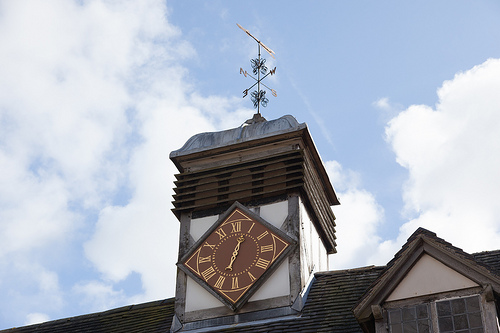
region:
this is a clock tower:
[116, 180, 287, 312]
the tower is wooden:
[73, 91, 345, 327]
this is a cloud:
[49, 73, 158, 215]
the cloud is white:
[11, 7, 105, 109]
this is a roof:
[343, 279, 352, 310]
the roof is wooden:
[337, 289, 345, 321]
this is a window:
[405, 306, 434, 325]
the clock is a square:
[207, 228, 255, 320]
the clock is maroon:
[215, 190, 287, 328]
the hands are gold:
[210, 247, 259, 328]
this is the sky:
[309, 19, 434, 80]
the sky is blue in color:
[368, 27, 449, 72]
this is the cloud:
[398, 95, 487, 184]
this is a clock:
[190, 226, 270, 283]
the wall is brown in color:
[240, 245, 258, 262]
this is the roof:
[328, 259, 363, 316]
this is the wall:
[412, 258, 462, 290]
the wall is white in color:
[418, 266, 443, 290]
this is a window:
[442, 301, 480, 331]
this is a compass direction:
[231, 13, 293, 64]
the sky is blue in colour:
[333, 53, 460, 151]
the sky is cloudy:
[313, 44, 465, 213]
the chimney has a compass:
[204, 29, 281, 120]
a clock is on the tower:
[185, 192, 293, 310]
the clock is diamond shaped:
[193, 193, 303, 316]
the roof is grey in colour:
[86, 298, 144, 331]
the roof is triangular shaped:
[356, 232, 496, 329]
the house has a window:
[390, 295, 497, 331]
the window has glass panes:
[378, 280, 477, 330]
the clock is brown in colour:
[218, 216, 270, 298]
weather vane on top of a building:
[238, 23, 284, 110]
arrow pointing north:
[237, 20, 274, 57]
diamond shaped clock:
[181, 206, 300, 302]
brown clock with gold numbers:
[178, 205, 294, 310]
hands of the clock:
[222, 234, 244, 271]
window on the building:
[392, 294, 483, 331]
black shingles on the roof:
[2, 247, 494, 331]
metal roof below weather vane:
[164, 115, 307, 156]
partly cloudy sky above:
[2, 4, 499, 302]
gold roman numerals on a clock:
[198, 218, 274, 290]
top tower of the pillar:
[222, 24, 290, 125]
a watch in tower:
[166, 180, 308, 320]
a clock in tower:
[164, 200, 313, 327]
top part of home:
[371, 209, 476, 326]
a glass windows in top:
[381, 294, 493, 331]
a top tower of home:
[177, 23, 332, 320]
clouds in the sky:
[36, 15, 203, 277]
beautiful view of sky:
[16, 8, 480, 163]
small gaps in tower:
[216, 147, 275, 211]